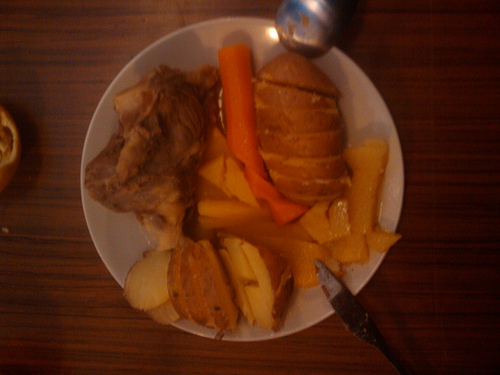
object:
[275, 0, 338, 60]
spoon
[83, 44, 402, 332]
dinner meal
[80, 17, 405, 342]
plate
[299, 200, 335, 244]
potato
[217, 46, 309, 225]
carrot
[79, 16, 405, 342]
plastic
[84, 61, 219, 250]
meat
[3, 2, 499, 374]
table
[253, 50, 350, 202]
bread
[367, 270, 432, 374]
shadow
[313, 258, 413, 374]
knife